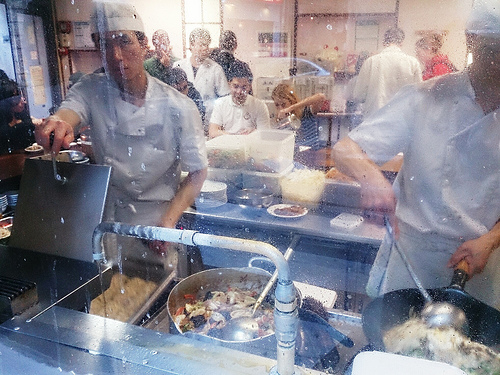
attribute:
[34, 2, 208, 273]
man — cooking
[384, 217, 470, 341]
spoon — large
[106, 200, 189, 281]
apron — white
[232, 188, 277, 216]
bowl — steel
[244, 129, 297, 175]
container — white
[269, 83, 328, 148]
woman — back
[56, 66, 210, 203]
shirt — white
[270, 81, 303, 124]
hair — red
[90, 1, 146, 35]
hat — white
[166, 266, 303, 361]
pot — silver, halffull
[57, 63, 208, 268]
uniform — white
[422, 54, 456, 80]
cloth — red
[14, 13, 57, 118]
door — glass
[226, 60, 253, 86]
hair — black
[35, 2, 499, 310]
men — cooking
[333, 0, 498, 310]
guy — stirring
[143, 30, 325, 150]
people — ordering, waiting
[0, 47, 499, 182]
area — dining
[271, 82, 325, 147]
person — pouring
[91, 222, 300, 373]
faucet — grey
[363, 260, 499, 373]
pan — he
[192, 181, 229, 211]
plates — stacked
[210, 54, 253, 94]
shirt — black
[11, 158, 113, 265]
lid — lifted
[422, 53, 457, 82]
top — red